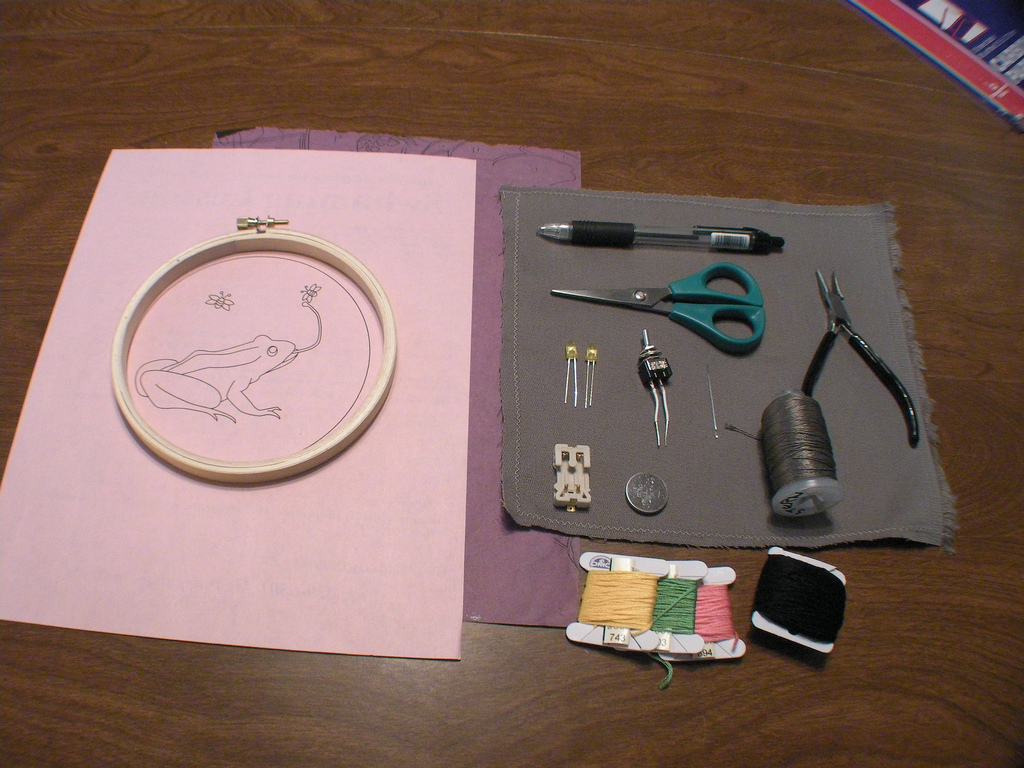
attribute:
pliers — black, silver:
[755, 273, 937, 474]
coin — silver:
[599, 471, 693, 547]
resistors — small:
[519, 331, 615, 412]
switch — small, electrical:
[619, 320, 721, 446]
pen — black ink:
[535, 178, 797, 289]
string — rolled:
[552, 560, 836, 692]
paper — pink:
[12, 91, 497, 683]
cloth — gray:
[491, 167, 1004, 576]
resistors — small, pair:
[530, 335, 664, 448]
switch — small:
[639, 325, 678, 446]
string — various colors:
[564, 545, 843, 664]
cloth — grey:
[503, 188, 938, 551]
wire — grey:
[760, 392, 838, 520]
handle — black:
[803, 329, 929, 446]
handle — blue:
[672, 256, 768, 358]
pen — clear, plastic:
[542, 219, 782, 250]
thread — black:
[752, 547, 846, 658]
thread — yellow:
[568, 554, 657, 652]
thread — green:
[656, 573, 702, 640]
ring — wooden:
[110, 232, 400, 481]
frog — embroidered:
[138, 327, 309, 423]